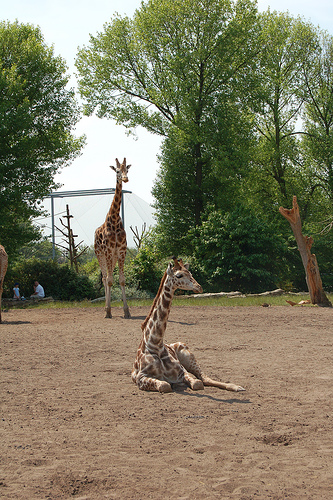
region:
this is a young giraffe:
[90, 146, 154, 336]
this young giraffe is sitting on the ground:
[115, 237, 252, 426]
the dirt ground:
[54, 415, 211, 484]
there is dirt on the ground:
[187, 418, 295, 496]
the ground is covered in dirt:
[14, 365, 131, 471]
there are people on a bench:
[3, 276, 61, 314]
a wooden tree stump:
[268, 185, 331, 308]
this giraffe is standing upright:
[82, 134, 160, 320]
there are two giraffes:
[79, 139, 263, 419]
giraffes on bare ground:
[67, 165, 232, 415]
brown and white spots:
[128, 260, 207, 412]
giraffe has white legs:
[158, 352, 273, 425]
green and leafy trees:
[143, 10, 294, 295]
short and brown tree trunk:
[277, 172, 325, 307]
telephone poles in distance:
[57, 201, 86, 266]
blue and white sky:
[57, 36, 123, 173]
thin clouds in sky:
[56, 38, 113, 141]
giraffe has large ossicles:
[109, 148, 128, 175]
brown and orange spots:
[98, 209, 131, 261]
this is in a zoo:
[18, 71, 323, 354]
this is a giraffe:
[115, 247, 248, 380]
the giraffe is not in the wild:
[118, 256, 239, 413]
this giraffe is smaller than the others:
[133, 262, 224, 408]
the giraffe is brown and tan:
[118, 258, 217, 409]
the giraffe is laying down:
[142, 255, 212, 418]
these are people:
[13, 272, 64, 316]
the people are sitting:
[9, 275, 64, 318]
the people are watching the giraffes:
[11, 259, 60, 309]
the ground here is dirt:
[60, 366, 174, 475]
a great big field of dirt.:
[4, 406, 229, 498]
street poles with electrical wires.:
[38, 199, 81, 270]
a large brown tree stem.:
[276, 195, 331, 308]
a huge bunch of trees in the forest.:
[154, 0, 276, 254]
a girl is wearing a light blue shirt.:
[13, 288, 21, 296]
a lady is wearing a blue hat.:
[9, 280, 22, 287]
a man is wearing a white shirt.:
[36, 286, 42, 292]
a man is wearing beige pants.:
[28, 292, 44, 301]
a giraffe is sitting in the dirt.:
[124, 253, 246, 393]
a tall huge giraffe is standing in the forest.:
[88, 154, 138, 320]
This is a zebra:
[126, 249, 247, 415]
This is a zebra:
[88, 148, 147, 329]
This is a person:
[27, 277, 51, 302]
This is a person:
[8, 278, 23, 302]